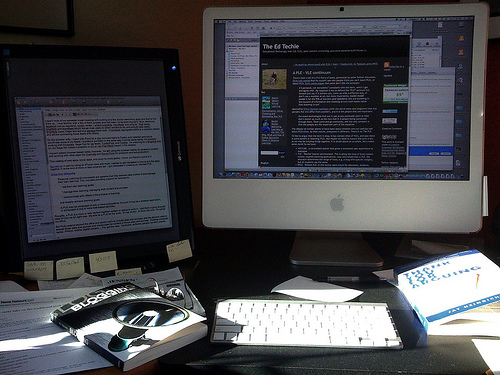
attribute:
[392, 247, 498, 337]
book — visible.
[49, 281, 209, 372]
book — visible.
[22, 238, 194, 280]
notes — yellow.